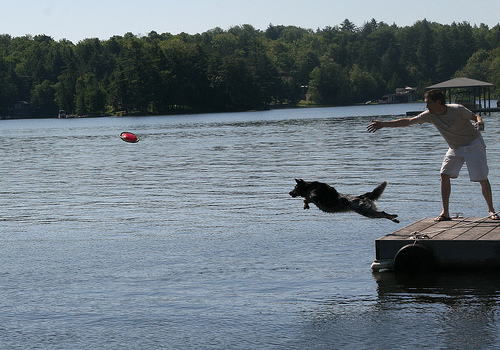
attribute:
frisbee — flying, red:
[119, 130, 139, 144]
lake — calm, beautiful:
[0, 99, 498, 350]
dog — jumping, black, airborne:
[288, 178, 401, 224]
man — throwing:
[366, 89, 499, 222]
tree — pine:
[271, 75, 287, 105]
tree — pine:
[248, 50, 279, 108]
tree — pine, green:
[108, 68, 132, 114]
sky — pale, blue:
[0, 1, 498, 46]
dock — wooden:
[371, 216, 499, 272]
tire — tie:
[393, 243, 436, 278]